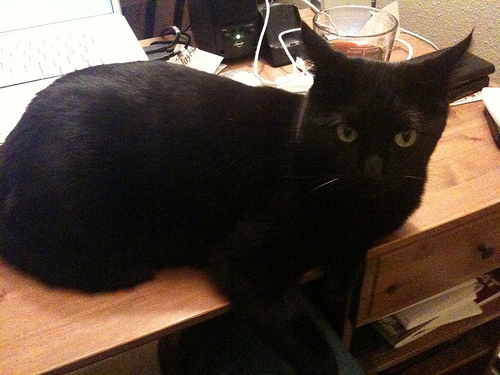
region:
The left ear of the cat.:
[298, 24, 337, 76]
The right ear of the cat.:
[412, 28, 475, 81]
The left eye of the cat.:
[334, 119, 364, 147]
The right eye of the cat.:
[389, 120, 418, 150]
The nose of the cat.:
[359, 148, 382, 170]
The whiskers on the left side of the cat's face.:
[311, 160, 347, 195]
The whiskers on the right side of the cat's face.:
[400, 166, 435, 191]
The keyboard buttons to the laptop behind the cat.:
[2, 31, 147, 77]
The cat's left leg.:
[237, 281, 343, 373]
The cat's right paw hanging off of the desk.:
[336, 245, 360, 305]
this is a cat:
[120, 70, 394, 184]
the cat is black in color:
[164, 143, 240, 177]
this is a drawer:
[399, 248, 487, 278]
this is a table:
[11, 311, 54, 344]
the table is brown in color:
[26, 312, 101, 352]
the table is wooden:
[66, 311, 143, 356]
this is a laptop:
[33, 22, 124, 53]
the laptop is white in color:
[112, 14, 123, 54]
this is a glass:
[325, 12, 410, 47]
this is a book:
[403, 305, 443, 324]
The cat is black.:
[46, 34, 433, 291]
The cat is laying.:
[30, 34, 406, 297]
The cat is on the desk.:
[21, 39, 474, 301]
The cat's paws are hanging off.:
[23, 12, 485, 372]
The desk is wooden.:
[440, 137, 486, 297]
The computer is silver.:
[2, 4, 129, 113]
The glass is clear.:
[311, 4, 394, 79]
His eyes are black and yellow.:
[325, 98, 445, 158]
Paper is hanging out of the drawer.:
[375, 283, 497, 358]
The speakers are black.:
[183, 7, 296, 80]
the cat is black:
[146, 52, 367, 272]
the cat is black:
[87, 95, 427, 337]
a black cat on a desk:
[5, 25, 484, 361]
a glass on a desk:
[310, 4, 413, 91]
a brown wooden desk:
[3, 7, 497, 372]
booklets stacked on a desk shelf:
[377, 270, 498, 348]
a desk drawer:
[362, 203, 498, 329]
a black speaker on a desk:
[184, 0, 269, 62]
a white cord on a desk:
[244, 2, 470, 92]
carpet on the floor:
[321, 1, 498, 79]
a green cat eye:
[325, 117, 356, 143]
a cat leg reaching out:
[218, 254, 360, 374]